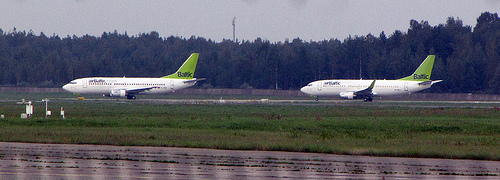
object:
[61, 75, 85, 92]
nose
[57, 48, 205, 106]
plane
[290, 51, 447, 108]
plane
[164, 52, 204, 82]
tail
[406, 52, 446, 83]
tail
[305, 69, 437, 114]
plane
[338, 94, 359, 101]
engine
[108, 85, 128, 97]
engine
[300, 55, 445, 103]
airplane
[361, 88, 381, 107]
motorcycle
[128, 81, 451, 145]
grass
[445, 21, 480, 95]
tree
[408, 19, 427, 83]
tree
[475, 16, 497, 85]
tree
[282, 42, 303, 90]
tree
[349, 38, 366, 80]
tree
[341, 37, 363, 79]
tree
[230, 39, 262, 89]
tree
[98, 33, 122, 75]
tree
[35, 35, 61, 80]
tree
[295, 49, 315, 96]
tree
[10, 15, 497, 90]
trees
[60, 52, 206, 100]
airplane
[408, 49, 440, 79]
tail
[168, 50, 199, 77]
tail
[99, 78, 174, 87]
windows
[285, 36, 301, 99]
tree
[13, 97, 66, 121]
devices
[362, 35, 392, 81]
tree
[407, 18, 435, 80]
tree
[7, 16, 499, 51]
trees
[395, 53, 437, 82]
tail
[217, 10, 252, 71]
flag pole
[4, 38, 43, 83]
tree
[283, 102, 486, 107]
asphalt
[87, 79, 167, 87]
windows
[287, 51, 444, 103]
airplane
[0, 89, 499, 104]
runway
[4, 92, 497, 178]
runway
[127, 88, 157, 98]
wing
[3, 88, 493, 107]
runway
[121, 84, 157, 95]
wing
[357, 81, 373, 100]
wing